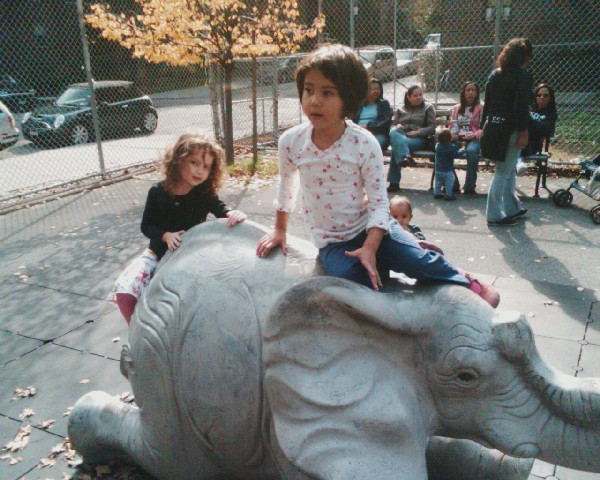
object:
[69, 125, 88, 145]
tire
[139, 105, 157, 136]
tire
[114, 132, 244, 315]
girl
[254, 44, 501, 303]
girl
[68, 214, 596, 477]
elephant statue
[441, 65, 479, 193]
woman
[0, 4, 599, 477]
park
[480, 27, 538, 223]
people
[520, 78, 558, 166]
person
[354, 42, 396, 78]
car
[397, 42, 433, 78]
car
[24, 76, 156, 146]
car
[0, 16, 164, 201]
street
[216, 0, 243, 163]
tree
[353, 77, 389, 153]
person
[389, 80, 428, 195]
people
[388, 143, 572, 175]
bench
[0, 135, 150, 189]
road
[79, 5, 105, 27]
leaves